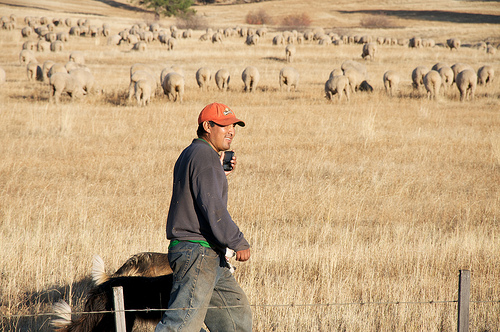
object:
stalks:
[349, 207, 360, 249]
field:
[1, 0, 498, 330]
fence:
[0, 268, 499, 330]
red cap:
[196, 102, 244, 129]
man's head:
[195, 104, 239, 150]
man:
[155, 102, 263, 331]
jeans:
[154, 237, 255, 330]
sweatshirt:
[167, 140, 247, 258]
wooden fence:
[0, 270, 499, 331]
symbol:
[223, 107, 234, 116]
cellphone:
[223, 150, 235, 170]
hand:
[219, 151, 236, 174]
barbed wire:
[126, 301, 457, 311]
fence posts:
[112, 286, 128, 331]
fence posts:
[457, 270, 471, 331]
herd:
[0, 13, 499, 105]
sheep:
[355, 35, 379, 59]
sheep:
[383, 69, 396, 93]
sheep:
[215, 68, 233, 90]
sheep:
[477, 65, 493, 86]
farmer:
[156, 102, 255, 331]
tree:
[361, 15, 406, 27]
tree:
[283, 12, 311, 30]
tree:
[174, 12, 207, 28]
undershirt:
[165, 236, 215, 246]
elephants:
[323, 67, 349, 101]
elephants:
[276, 64, 303, 89]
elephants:
[239, 65, 260, 91]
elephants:
[193, 67, 213, 88]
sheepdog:
[47, 260, 235, 330]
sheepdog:
[89, 245, 236, 284]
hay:
[0, 98, 499, 329]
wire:
[14, 300, 457, 318]